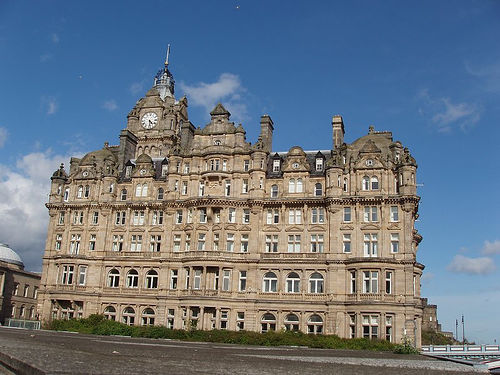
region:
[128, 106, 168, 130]
Clock on a tower.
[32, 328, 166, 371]
The ground is paved.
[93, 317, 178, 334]
The grass is green.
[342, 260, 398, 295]
The castle has bay windows.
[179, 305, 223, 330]
The castle has pillars.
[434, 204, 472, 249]
The sky is blue.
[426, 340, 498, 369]
The bridge is grey.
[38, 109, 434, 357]
The castle is tan.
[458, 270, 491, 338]
There are clouds in the sky.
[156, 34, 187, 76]
A flag on a pole.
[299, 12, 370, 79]
part of the sky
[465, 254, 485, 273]
part of a cloud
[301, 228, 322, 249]
part of a window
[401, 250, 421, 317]
edge of a building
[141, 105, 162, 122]
part of a clock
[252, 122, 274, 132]
tip of the building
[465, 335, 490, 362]
part of a bridge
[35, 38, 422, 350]
the building has seven floors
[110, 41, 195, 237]
a clock tower is on the building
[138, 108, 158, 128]
the clock has black hands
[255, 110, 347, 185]
two chimneys are on the building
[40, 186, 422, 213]
parapets are on the building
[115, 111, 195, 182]
chimneys are on the side of the building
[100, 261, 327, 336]
arched windows are on the side of the structure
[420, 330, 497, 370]
a bridge is near the building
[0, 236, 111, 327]
a dome is next door to the building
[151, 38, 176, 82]
a cupula is on top of the clock tower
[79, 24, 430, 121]
sky is blue and cloudy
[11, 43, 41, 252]
sky is blue and cloudy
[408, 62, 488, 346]
sky is blue and cloudy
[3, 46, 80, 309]
sky is blue and cloudy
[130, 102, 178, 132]
clockface is black and white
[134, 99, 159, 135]
clockface is black and white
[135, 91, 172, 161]
clockface is black and white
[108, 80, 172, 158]
clockface is black and white